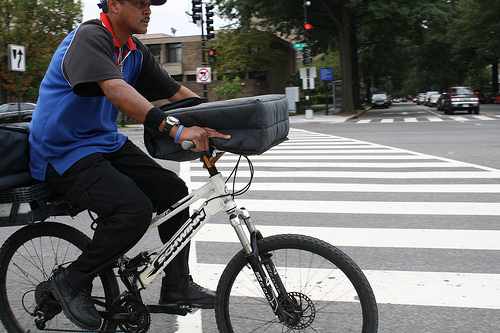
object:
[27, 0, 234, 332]
man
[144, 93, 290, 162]
pizza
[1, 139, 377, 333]
bike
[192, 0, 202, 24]
traffic signal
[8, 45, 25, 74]
sign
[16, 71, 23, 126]
pole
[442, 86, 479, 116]
car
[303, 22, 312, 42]
traffic signal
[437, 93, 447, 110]
car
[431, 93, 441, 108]
car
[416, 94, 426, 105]
car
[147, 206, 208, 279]
logo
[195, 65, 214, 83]
sign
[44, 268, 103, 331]
shoe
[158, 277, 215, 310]
shoe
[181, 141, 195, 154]
handle bar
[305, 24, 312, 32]
light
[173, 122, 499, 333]
crosswalk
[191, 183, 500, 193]
line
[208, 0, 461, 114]
tree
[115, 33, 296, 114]
building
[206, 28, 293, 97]
tree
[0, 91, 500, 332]
street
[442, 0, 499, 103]
tree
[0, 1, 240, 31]
sky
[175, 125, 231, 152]
hand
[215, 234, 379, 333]
tire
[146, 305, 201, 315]
pedal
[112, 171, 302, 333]
frame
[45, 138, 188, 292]
pants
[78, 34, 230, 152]
arm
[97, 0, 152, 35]
head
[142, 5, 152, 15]
nose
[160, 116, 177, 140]
watch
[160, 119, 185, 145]
wrist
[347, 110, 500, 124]
crosswalk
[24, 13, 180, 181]
shirt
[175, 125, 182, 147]
wristband